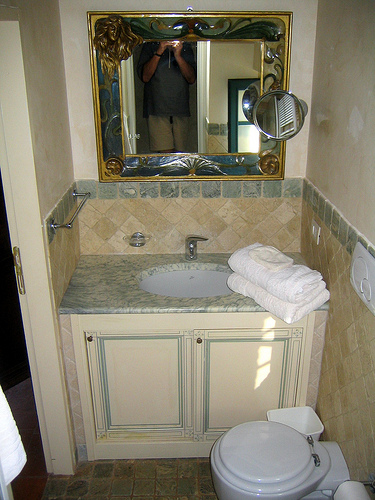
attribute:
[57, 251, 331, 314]
countertop — marble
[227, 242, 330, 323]
towels — folded, stacked, white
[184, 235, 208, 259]
sink fixture — silver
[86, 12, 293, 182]
mirror — decorative, square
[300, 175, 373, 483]
wall — tan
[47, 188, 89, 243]
handle — silver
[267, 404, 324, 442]
trash can — white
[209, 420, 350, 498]
toilet — round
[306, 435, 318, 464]
toilet hinges — round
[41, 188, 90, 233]
handle — silver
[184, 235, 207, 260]
faucet — silver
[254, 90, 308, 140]
mirror — round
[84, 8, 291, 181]
mirror border — yellow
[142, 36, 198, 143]
man — black shirt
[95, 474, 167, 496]
floor — cemented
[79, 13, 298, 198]
mirror — clear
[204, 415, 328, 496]
cover — white toilet 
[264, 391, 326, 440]
gabag can — white 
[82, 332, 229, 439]
drawers — yellow , scene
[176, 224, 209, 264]
water — silver tap 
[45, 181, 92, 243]
towel holder — silver 